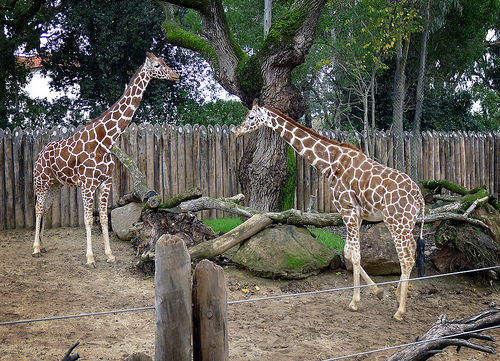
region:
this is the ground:
[23, 270, 67, 306]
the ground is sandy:
[15, 269, 74, 307]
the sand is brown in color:
[58, 278, 132, 303]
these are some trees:
[167, 0, 498, 132]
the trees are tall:
[311, 5, 491, 120]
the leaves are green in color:
[433, 27, 464, 62]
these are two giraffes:
[25, 50, 433, 328]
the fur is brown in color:
[344, 163, 379, 192]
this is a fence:
[151, 129, 213, 185]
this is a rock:
[226, 223, 329, 275]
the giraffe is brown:
[237, 87, 432, 346]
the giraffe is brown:
[29, 35, 253, 261]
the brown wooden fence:
[160, 121, 186, 211]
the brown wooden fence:
[174, 89, 255, 207]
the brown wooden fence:
[397, 122, 466, 233]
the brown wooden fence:
[157, 107, 210, 272]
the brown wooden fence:
[182, 112, 267, 289]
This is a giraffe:
[216, 96, 443, 326]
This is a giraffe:
[17, 45, 193, 283]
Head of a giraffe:
[233, 92, 276, 147]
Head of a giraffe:
[132, 44, 188, 89]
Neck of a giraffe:
[267, 99, 328, 180]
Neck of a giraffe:
[85, 42, 147, 147]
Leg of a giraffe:
[98, 183, 123, 269]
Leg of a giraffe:
[78, 180, 98, 277]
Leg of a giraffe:
[25, 178, 42, 260]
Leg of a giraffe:
[341, 210, 363, 324]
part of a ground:
[276, 311, 293, 336]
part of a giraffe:
[343, 194, 376, 226]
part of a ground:
[273, 330, 299, 360]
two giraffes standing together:
[9, 50, 423, 309]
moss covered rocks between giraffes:
[225, 221, 342, 283]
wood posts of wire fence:
[142, 233, 235, 356]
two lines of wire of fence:
[0, 265, 497, 360]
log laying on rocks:
[176, 192, 499, 267]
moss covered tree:
[172, 11, 311, 231]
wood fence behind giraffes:
[2, 118, 494, 230]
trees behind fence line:
[8, 7, 482, 114]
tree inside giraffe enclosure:
[160, 5, 329, 217]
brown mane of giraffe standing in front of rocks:
[264, 100, 358, 149]